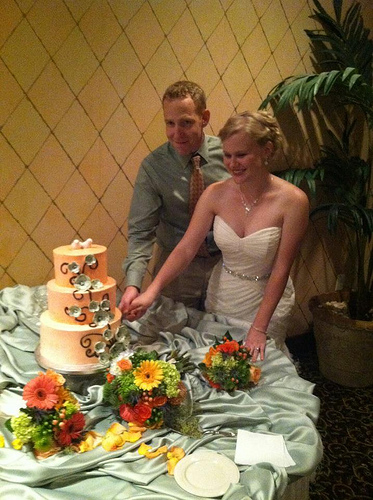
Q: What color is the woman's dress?
A: White.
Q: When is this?
A: A wedding.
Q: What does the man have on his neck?
A: A neck tie.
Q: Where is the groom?
A: Behind the bride.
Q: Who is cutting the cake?
A: The bride and groom.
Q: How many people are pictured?
A: Two.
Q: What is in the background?
A: A plant.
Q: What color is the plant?
A: Green.